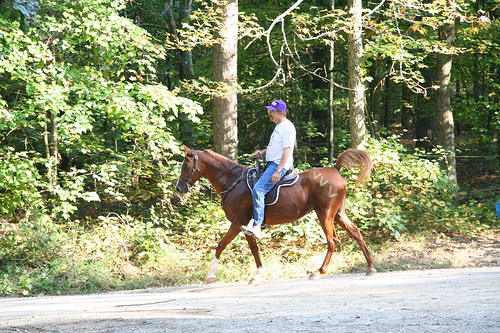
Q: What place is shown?
A: It is a forest.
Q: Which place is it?
A: It is a forest.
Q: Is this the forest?
A: Yes, it is the forest.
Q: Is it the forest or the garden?
A: It is the forest.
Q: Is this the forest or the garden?
A: It is the forest.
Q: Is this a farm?
A: No, it is a forest.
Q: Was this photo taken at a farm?
A: No, the picture was taken in a forest.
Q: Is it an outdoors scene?
A: Yes, it is outdoors.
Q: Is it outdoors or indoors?
A: It is outdoors.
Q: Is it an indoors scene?
A: No, it is outdoors.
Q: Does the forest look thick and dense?
A: Yes, the forest is thick and dense.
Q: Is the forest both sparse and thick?
A: No, the forest is thick but dense.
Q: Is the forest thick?
A: Yes, the forest is thick.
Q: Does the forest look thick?
A: Yes, the forest is thick.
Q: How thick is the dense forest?
A: The forest is thick.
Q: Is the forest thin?
A: No, the forest is thick.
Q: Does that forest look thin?
A: No, the forest is thick.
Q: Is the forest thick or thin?
A: The forest is thick.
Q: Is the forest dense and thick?
A: Yes, the forest is dense and thick.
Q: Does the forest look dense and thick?
A: Yes, the forest is dense and thick.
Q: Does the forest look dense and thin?
A: No, the forest is dense but thick.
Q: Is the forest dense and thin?
A: No, the forest is dense but thick.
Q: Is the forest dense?
A: Yes, the forest is dense.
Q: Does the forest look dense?
A: Yes, the forest is dense.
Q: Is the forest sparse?
A: No, the forest is dense.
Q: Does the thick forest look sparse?
A: No, the forest is dense.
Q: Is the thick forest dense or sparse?
A: The forest is dense.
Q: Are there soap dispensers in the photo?
A: No, there are no soap dispensers.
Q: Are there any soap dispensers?
A: No, there are no soap dispensers.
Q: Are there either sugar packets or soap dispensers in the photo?
A: No, there are no soap dispensers or sugar packets.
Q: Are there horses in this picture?
A: Yes, there is a horse.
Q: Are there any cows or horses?
A: Yes, there is a horse.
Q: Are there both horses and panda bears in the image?
A: No, there is a horse but no pandas.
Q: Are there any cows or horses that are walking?
A: Yes, the horse is walking.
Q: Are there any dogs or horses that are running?
A: Yes, the horse is running.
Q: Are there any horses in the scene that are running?
A: Yes, there is a horse that is running.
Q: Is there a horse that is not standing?
A: Yes, there is a horse that is running.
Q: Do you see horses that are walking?
A: Yes, there is a horse that is walking.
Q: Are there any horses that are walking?
A: Yes, there is a horse that is walking.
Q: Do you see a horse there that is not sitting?
A: Yes, there is a horse that is walking .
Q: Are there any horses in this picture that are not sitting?
A: Yes, there is a horse that is walking.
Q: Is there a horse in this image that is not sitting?
A: Yes, there is a horse that is walking.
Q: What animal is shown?
A: The animal is a horse.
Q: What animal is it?
A: The animal is a horse.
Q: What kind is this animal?
A: This is a horse.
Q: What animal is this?
A: This is a horse.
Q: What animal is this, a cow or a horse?
A: This is a horse.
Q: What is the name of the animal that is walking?
A: The animal is a horse.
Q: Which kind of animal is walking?
A: The animal is a horse.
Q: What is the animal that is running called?
A: The animal is a horse.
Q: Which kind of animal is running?
A: The animal is a horse.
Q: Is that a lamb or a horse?
A: That is a horse.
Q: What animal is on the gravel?
A: The horse is on the gravel.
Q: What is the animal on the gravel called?
A: The animal is a horse.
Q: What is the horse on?
A: The horse is on the gravel.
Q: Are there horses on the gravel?
A: Yes, there is a horse on the gravel.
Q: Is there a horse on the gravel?
A: Yes, there is a horse on the gravel.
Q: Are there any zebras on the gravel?
A: No, there is a horse on the gravel.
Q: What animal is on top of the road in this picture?
A: The horse is on top of the road.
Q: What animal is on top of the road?
A: The horse is on top of the road.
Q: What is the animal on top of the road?
A: The animal is a horse.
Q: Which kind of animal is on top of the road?
A: The animal is a horse.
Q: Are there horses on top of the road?
A: Yes, there is a horse on top of the road.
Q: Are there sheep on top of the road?
A: No, there is a horse on top of the road.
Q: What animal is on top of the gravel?
A: The horse is on top of the gravel.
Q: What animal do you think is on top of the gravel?
A: The animal is a horse.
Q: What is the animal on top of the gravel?
A: The animal is a horse.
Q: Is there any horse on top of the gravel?
A: Yes, there is a horse on top of the gravel.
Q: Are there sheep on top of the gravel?
A: No, there is a horse on top of the gravel.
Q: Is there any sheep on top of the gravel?
A: No, there is a horse on top of the gravel.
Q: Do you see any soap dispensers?
A: No, there are no soap dispensers.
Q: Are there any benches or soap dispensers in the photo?
A: No, there are no soap dispensers or benches.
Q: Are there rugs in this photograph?
A: No, there are no rugs.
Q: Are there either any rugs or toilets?
A: No, there are no rugs or toilets.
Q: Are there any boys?
A: No, there are no boys.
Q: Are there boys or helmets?
A: No, there are no boys or helmets.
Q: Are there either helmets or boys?
A: No, there are no boys or helmets.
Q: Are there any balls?
A: No, there are no balls.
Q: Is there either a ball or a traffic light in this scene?
A: No, there are no balls or traffic lights.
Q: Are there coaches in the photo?
A: No, there are no coaches.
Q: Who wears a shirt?
A: The man wears a shirt.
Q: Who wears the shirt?
A: The man wears a shirt.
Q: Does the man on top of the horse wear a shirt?
A: Yes, the man wears a shirt.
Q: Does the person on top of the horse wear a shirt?
A: Yes, the man wears a shirt.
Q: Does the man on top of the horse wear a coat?
A: No, the man wears a shirt.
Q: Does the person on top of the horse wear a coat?
A: No, the man wears a shirt.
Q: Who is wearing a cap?
A: The man is wearing a cap.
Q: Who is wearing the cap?
A: The man is wearing a cap.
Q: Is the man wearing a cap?
A: Yes, the man is wearing a cap.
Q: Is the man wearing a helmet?
A: No, the man is wearing a cap.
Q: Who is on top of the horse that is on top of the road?
A: The man is on top of the horse.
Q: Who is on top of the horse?
A: The man is on top of the horse.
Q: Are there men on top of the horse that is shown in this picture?
A: Yes, there is a man on top of the horse.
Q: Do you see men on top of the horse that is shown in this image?
A: Yes, there is a man on top of the horse.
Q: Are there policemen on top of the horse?
A: No, there is a man on top of the horse.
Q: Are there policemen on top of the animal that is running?
A: No, there is a man on top of the horse.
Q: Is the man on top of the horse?
A: Yes, the man is on top of the horse.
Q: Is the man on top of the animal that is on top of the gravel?
A: Yes, the man is on top of the horse.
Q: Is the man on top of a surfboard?
A: No, the man is on top of the horse.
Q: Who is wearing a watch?
A: The man is wearing a watch.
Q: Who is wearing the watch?
A: The man is wearing a watch.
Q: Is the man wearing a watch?
A: Yes, the man is wearing a watch.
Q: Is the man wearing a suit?
A: No, the man is wearing a watch.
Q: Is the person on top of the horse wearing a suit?
A: No, the man is wearing a watch.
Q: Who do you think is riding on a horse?
A: The man is riding on a horse.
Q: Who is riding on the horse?
A: The man is riding on a horse.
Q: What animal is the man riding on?
A: The man is riding on a horse.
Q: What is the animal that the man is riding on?
A: The animal is a horse.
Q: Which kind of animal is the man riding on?
A: The man is riding on a horse.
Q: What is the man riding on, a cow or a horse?
A: The man is riding on a horse.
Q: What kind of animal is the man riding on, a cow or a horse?
A: The man is riding on a horse.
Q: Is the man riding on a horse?
A: Yes, the man is riding on a horse.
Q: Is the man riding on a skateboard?
A: No, the man is riding on a horse.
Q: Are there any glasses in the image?
A: No, there are no glasses.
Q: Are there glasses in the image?
A: No, there are no glasses.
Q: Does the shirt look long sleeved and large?
A: No, the shirt is large but short sleeved.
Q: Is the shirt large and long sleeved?
A: No, the shirt is large but short sleeved.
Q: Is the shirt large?
A: Yes, the shirt is large.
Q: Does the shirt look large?
A: Yes, the shirt is large.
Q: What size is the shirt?
A: The shirt is large.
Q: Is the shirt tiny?
A: No, the shirt is large.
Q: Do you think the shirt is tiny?
A: No, the shirt is large.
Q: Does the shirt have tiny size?
A: No, the shirt is large.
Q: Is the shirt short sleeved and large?
A: Yes, the shirt is short sleeved and large.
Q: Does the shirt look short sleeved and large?
A: Yes, the shirt is short sleeved and large.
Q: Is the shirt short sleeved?
A: Yes, the shirt is short sleeved.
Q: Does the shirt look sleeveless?
A: No, the shirt is short sleeved.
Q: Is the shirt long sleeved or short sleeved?
A: The shirt is short sleeved.